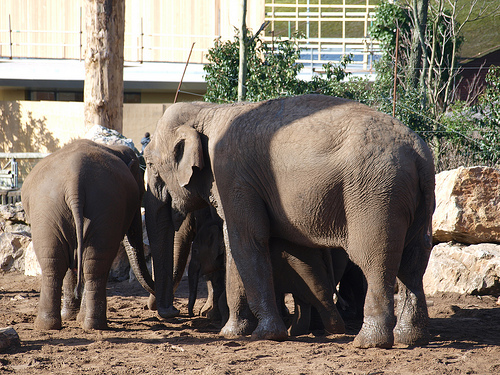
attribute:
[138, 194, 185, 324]
trunk — brown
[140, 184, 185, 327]
trunk — hanging down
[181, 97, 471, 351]
elephant — baby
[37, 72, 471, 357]
elephants — grey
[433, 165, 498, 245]
rock — stacked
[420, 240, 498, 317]
rock — stacked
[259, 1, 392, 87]
building — tall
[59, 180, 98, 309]
tail — brown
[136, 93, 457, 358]
elephant — adult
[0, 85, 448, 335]
elephants — standing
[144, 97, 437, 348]
elephant — bigger, huge, adult, standing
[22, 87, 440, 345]
elephants — standing, gray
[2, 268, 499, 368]
ground — muddy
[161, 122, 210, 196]
ear — big, floppy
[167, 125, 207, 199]
elephant's ear — big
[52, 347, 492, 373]
ground — muddy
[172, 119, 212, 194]
ear — large, gray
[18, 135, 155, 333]
elephant — small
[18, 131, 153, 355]
elephant — small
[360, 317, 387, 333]
marks — white